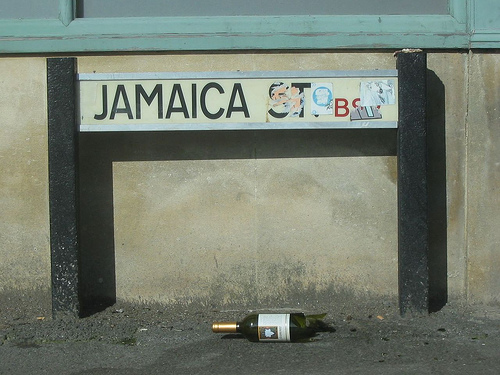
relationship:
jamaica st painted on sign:
[91, 80, 311, 119] [74, 76, 399, 125]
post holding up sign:
[40, 54, 82, 316] [75, 70, 397, 132]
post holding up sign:
[395, 46, 431, 316] [75, 70, 397, 132]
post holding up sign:
[395, 46, 431, 316] [408, 173, 438, 270]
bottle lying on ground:
[192, 297, 359, 335] [0, 308, 484, 373]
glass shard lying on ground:
[291, 307, 335, 341] [0, 308, 484, 373]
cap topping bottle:
[209, 317, 239, 337] [207, 307, 312, 345]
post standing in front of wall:
[40, 54, 82, 316] [2, 60, 491, 297]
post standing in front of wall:
[395, 46, 431, 316] [2, 60, 491, 297]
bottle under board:
[192, 297, 359, 335] [49, 49, 494, 170]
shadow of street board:
[155, 324, 356, 371] [35, 50, 445, 312]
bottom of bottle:
[291, 312, 308, 340] [211, 310, 308, 339]